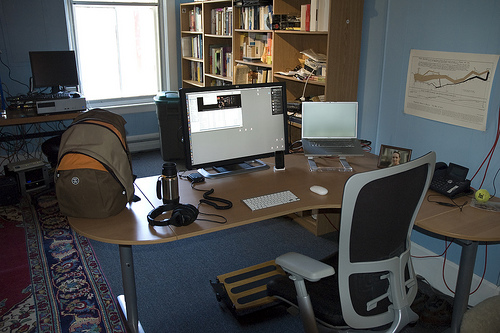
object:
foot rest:
[210, 257, 302, 324]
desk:
[64, 147, 496, 329]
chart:
[400, 46, 499, 133]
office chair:
[266, 150, 438, 333]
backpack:
[55, 106, 133, 218]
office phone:
[428, 159, 471, 199]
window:
[71, 4, 163, 100]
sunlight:
[83, 8, 155, 94]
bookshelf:
[269, 32, 331, 88]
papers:
[297, 48, 325, 62]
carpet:
[2, 197, 126, 331]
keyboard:
[237, 189, 302, 212]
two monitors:
[180, 81, 365, 179]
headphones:
[147, 201, 199, 227]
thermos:
[154, 160, 181, 204]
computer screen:
[185, 86, 284, 164]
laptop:
[302, 102, 366, 158]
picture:
[375, 142, 414, 168]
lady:
[388, 150, 403, 166]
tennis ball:
[471, 188, 492, 203]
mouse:
[308, 183, 329, 196]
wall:
[365, 2, 497, 175]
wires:
[194, 181, 235, 224]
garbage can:
[151, 89, 184, 163]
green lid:
[153, 88, 185, 106]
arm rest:
[273, 251, 335, 281]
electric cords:
[464, 119, 500, 192]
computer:
[177, 78, 290, 181]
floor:
[3, 200, 318, 333]